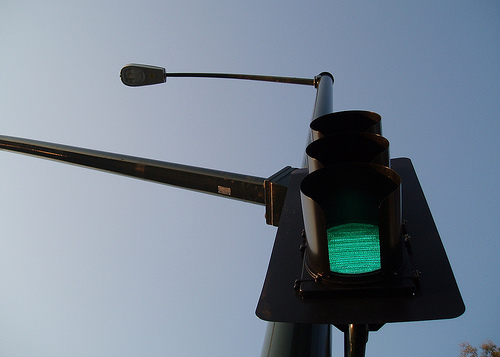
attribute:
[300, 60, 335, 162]
post — black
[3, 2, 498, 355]
sky — blue, clear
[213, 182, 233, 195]
sticker — white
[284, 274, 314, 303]
bolt — black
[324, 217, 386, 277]
light — green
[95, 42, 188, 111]
lamp — for street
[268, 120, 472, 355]
light — big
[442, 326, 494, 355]
tree — lower right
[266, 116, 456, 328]
light — black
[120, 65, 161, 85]
bulb — unlit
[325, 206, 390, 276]
bulb — green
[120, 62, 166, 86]
light — big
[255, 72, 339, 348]
pole — tall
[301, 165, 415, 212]
cover — circular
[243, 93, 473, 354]
light — big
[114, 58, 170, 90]
light — big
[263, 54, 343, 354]
pole — tall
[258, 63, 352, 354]
pole — tall, black